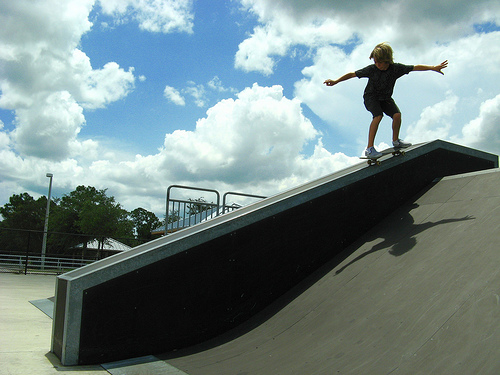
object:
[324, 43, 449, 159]
kid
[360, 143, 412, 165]
skateboard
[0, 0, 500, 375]
picture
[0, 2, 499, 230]
sky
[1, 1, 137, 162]
clouds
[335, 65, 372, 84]
arms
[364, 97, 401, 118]
shorts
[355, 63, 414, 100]
shirt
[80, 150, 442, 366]
wall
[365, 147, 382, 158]
feet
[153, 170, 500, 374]
ramp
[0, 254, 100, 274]
fence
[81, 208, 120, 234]
leaves